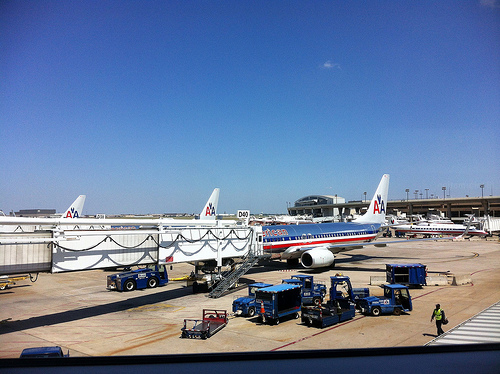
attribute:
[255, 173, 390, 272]
colored airplane — blue, white, red, silver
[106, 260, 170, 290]
service vehicle — blue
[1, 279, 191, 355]
runway — tan-colored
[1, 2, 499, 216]
sky is blue — clear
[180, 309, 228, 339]
luggage cart — empty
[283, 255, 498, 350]
passenger walkway — long, ramp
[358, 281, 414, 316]
transport truck — small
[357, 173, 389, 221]
plane tail — white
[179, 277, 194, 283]
traffic cone — orange, white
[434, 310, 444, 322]
vest — green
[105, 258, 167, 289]
machine — blue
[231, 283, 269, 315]
machine — blue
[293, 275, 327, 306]
machine — blue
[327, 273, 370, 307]
machine — blue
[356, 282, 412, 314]
machine — blue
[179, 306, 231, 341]
machine — red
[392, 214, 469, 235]
airplane — white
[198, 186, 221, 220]
airplane — white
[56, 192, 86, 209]
airplane — white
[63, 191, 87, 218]
airplane — American Airlines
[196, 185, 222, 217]
airplane — American Airlines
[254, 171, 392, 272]
airplane — white, silver, blue, American Airlines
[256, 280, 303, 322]
luggage cart — empty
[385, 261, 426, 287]
luggage cart — empty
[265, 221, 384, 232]
paint — silver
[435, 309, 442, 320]
vest — yellow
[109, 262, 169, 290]
vehicle — blue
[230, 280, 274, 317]
vehicle — blue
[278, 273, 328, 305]
vehicle — blue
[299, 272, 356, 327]
vehicle — blue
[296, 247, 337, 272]
engine — white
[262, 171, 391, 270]
plane — large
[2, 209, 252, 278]
ramp — white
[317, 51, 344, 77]
cloud — single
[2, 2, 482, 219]
sky — blue